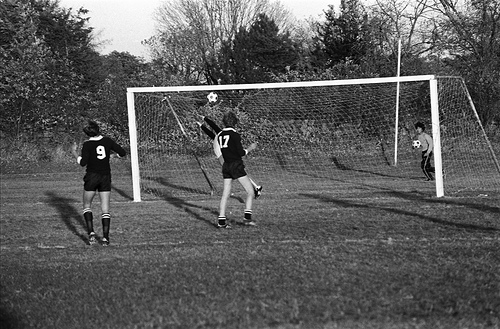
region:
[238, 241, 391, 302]
the grass on the soccer field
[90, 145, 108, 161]
the number 9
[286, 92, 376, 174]
a soccer goal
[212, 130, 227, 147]
number 17 on the jersey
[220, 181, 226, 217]
a person leg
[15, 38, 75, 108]
the bushes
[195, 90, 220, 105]
a soccer ball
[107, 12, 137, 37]
the sky is clear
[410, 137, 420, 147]
a person is holding a soccer ball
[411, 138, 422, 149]
a black and white soccer ball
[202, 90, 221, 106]
Soccer ball in midair.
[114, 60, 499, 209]
Soccer net on the ground.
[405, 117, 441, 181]
child carrying soccer ball.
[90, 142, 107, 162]
Number on the shirt.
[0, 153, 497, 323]
Grass covering the ground.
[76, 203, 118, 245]
Long socks on player.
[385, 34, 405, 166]
Pole in the ground.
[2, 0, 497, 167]
Trees in the background.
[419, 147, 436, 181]
Stripes on the pants.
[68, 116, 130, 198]
Black shorts on player.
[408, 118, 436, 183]
Boy holding a soccer ball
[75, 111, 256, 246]
Two players in black shirts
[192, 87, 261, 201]
Goalie failing to stop a ball going into the net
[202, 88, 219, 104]
Soccer ball going into a soccer net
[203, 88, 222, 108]
Soccer ball in the air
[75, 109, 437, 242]
Four people playing a soccer game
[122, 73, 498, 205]
Large soccer net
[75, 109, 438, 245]
Four people on a soccer field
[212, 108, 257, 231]
Person wearing short black shorts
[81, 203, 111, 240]
Pair of tall black socks with stripes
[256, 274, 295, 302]
green grass in field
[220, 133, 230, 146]
number seven on shirt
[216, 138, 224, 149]
number one on shirt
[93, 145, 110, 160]
number nine on shirt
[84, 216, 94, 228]
woman with black socks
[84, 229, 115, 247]
woman with black sneakers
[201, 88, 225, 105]
volley ball in net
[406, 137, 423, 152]
volley ball in boys hand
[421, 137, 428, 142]
boy shirt is beige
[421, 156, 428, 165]
boy wearing black pants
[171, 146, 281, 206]
this is a soccer field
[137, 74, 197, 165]
this is a soccer net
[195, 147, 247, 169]
this is the number 17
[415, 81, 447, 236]
this is a pole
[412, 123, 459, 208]
the pole is white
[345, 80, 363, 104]
the pole is metal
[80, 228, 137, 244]
the socks are long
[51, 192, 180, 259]
the socks are navy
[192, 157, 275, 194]
these are some black shorts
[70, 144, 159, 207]
this is a long sleeved shirt